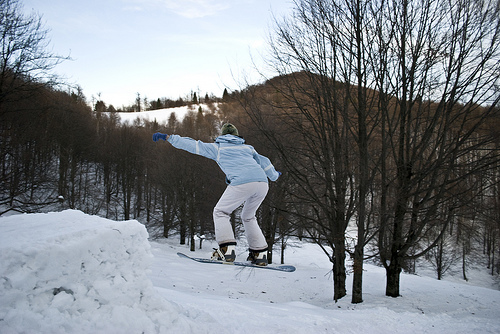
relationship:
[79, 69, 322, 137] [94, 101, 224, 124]
hill has snow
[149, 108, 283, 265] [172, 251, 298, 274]
person rides snowboard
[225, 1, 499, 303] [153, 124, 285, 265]
trees in front of person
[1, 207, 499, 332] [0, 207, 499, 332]
snow on ground